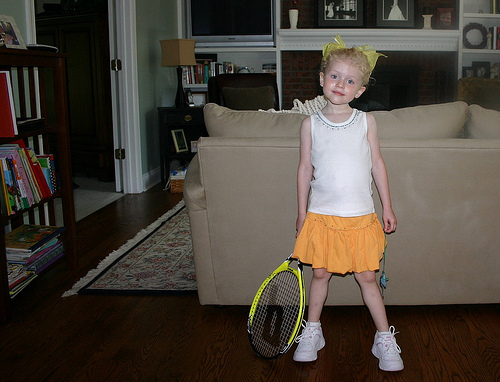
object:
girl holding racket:
[247, 43, 412, 374]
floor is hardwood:
[48, 299, 209, 369]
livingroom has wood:
[7, 5, 496, 378]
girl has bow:
[314, 38, 385, 115]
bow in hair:
[324, 36, 383, 71]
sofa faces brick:
[207, 45, 495, 186]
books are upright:
[0, 158, 15, 216]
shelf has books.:
[3, 43, 69, 209]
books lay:
[6, 274, 39, 297]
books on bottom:
[1, 222, 67, 253]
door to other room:
[28, 2, 143, 203]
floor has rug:
[68, 206, 200, 298]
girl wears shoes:
[367, 321, 410, 376]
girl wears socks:
[290, 311, 329, 365]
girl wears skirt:
[294, 208, 387, 282]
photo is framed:
[2, 12, 26, 54]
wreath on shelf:
[465, 18, 487, 58]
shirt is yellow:
[309, 106, 379, 219]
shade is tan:
[161, 37, 199, 71]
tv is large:
[209, 71, 288, 126]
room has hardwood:
[4, 178, 243, 355]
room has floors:
[111, 170, 496, 381]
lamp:
[162, 36, 195, 117]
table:
[148, 93, 200, 191]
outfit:
[291, 110, 393, 275]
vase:
[284, 8, 304, 28]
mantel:
[166, 1, 484, 101]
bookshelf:
[0, 2, 89, 296]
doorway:
[33, 4, 133, 208]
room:
[2, 0, 484, 359]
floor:
[65, 187, 194, 310]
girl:
[251, 30, 414, 380]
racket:
[241, 232, 318, 362]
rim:
[291, 281, 310, 347]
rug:
[63, 199, 201, 299]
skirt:
[293, 206, 389, 269]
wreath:
[460, 20, 489, 49]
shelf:
[460, 43, 498, 54]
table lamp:
[157, 38, 198, 107]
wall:
[127, 0, 183, 193]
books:
[1, 68, 21, 140]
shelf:
[0, 48, 77, 329]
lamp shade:
[156, 34, 198, 69]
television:
[185, 1, 273, 45]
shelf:
[189, 42, 279, 53]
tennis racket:
[249, 249, 304, 361]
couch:
[183, 101, 498, 305]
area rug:
[61, 196, 198, 299]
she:
[290, 39, 406, 375]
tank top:
[303, 105, 375, 220]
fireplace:
[280, 51, 455, 112]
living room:
[2, 1, 498, 379]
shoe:
[372, 324, 406, 375]